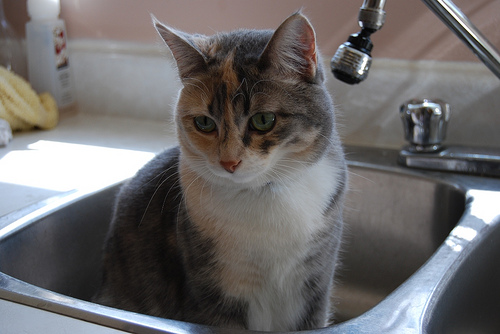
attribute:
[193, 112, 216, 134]
eye — green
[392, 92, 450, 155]
knob — chrome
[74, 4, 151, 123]
wall — brown and white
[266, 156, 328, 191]
whiskers — white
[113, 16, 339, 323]
cat — sitting, black, tan, white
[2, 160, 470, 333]
sink — empty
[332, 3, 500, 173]
faucet — adjustable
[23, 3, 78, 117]
bottle — empty, hand soap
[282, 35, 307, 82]
hair — white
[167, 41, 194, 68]
hair — white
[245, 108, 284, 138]
eye — big, green, gray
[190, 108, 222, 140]
eye — big, green, gray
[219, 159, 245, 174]
nose — pink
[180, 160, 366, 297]
chest — white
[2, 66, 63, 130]
towel — yellow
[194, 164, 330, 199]
neck — white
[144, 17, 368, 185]
head — brown, gray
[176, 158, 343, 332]
patch — white